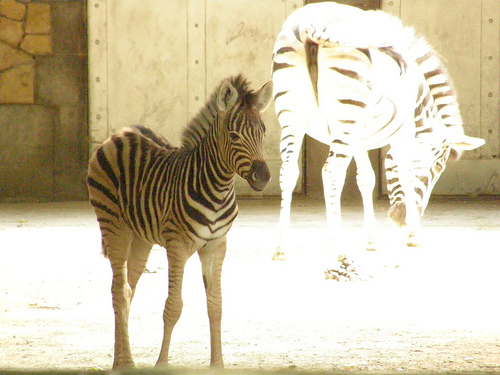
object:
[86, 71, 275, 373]
zebra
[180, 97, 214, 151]
mane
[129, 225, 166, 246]
underside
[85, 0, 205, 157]
door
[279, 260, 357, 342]
dirt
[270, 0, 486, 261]
zebra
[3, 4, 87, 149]
wall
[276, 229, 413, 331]
light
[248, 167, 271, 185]
snout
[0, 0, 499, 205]
building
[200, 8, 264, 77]
wall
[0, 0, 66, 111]
art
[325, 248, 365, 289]
rocks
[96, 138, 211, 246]
body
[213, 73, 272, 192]
head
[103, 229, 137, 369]
legs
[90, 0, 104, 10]
rivets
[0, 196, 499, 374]
ground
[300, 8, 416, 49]
tail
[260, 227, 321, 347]
sunlight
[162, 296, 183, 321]
knees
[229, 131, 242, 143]
eye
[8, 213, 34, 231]
stones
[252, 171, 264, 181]
nostril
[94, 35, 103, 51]
screws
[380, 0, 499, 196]
door